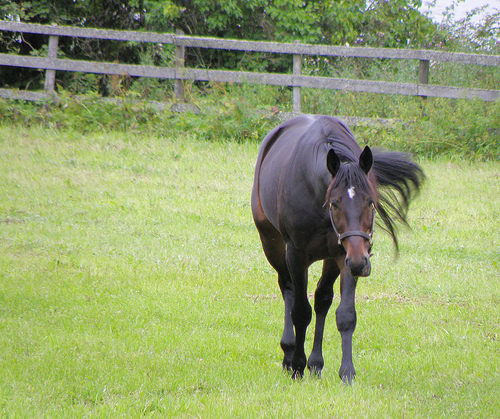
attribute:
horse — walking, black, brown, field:
[217, 102, 431, 390]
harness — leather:
[321, 223, 382, 248]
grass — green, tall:
[448, 167, 493, 192]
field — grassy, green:
[47, 145, 124, 254]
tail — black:
[377, 151, 421, 228]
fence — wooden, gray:
[392, 50, 481, 113]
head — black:
[299, 143, 391, 282]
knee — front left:
[290, 288, 322, 330]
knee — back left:
[276, 279, 289, 292]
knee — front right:
[332, 301, 363, 343]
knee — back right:
[317, 275, 328, 322]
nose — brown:
[348, 245, 369, 280]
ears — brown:
[322, 142, 382, 178]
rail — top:
[190, 29, 366, 57]